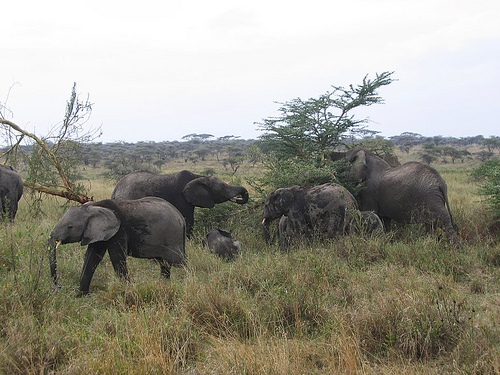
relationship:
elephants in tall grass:
[29, 129, 464, 298] [2, 260, 498, 367]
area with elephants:
[0, 148, 466, 295] [260, 182, 365, 246]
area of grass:
[0, 135, 500, 295] [334, 239, 436, 346]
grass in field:
[14, 172, 499, 372] [4, 190, 496, 372]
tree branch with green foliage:
[343, 110, 370, 127] [268, 71, 395, 163]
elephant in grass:
[261, 183, 360, 244] [304, 250, 394, 319]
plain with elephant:
[6, 176, 490, 373] [201, 227, 236, 263]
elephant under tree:
[323, 149, 466, 244] [1, 85, 97, 202]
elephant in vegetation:
[196, 225, 244, 264] [0, 62, 497, 374]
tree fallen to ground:
[4, 110, 84, 217] [2, 169, 496, 374]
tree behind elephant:
[244, 68, 394, 189] [330, 136, 471, 235]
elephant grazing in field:
[327, 148, 463, 244] [0, 142, 497, 371]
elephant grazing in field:
[256, 180, 356, 243] [0, 142, 497, 371]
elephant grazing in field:
[108, 174, 248, 243] [0, 142, 497, 371]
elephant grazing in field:
[44, 197, 191, 302] [0, 142, 497, 371]